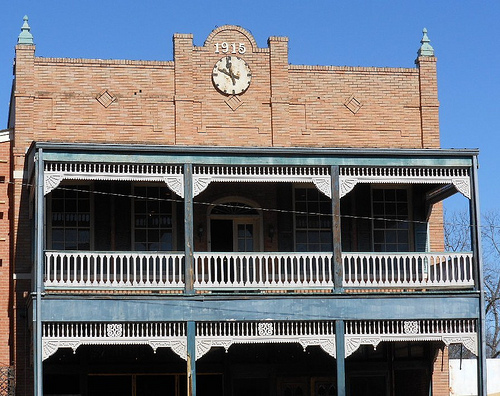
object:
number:
[214, 41, 222, 54]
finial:
[16, 11, 36, 49]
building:
[0, 12, 484, 389]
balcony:
[32, 140, 480, 296]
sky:
[0, 0, 500, 65]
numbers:
[236, 57, 241, 61]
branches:
[447, 219, 468, 251]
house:
[24, 140, 491, 394]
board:
[185, 320, 198, 394]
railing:
[340, 246, 471, 286]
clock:
[211, 54, 251, 97]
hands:
[226, 56, 238, 86]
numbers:
[220, 42, 229, 54]